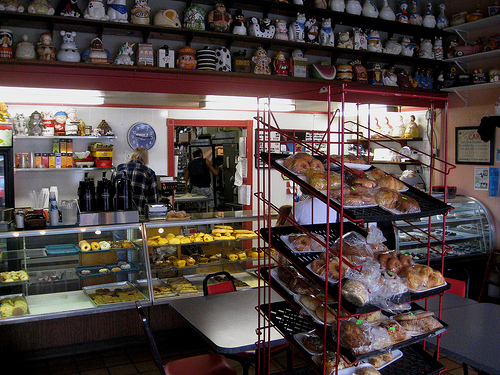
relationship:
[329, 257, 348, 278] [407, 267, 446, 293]
donut by bread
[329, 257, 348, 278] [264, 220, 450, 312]
donut on shelf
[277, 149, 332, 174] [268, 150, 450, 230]
bagels on shelf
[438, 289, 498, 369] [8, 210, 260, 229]
tables standing in front of counter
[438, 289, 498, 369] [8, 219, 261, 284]
tables standing in front of counter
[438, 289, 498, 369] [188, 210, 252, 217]
tables standing in front of counter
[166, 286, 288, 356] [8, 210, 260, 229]
tables standing in front of counter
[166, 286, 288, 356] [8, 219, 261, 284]
tables standing in front of counter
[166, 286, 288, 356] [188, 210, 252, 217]
tables standing in front of counter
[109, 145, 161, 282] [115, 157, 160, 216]
person wears plaid shirt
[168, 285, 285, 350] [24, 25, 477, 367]
table in bakery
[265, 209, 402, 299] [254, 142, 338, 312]
trays on shelf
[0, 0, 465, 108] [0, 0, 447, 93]
shelf of jars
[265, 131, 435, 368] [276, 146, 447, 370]
cart of baked goods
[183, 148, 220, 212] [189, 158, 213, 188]
man in a shirt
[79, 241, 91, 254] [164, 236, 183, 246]
pastry on a pastry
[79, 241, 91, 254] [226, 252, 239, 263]
pastry on a pastry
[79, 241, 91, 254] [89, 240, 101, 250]
pastry on a pastry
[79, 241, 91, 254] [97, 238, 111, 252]
pastry on a pastry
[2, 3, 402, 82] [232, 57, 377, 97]
various items on shelf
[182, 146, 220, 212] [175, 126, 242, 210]
man in room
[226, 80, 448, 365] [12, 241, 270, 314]
pastries on shelf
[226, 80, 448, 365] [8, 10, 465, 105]
pastries on shelf